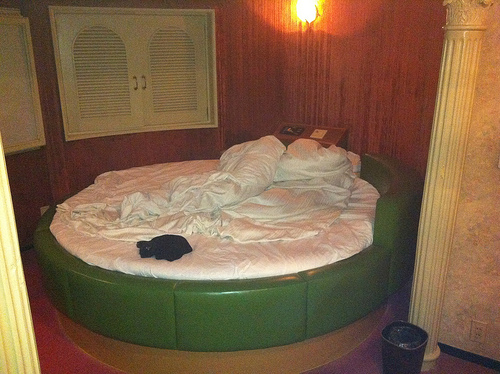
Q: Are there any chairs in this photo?
A: No, there are no chairs.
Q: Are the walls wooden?
A: Yes, the walls are wooden.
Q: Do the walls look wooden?
A: Yes, the walls are wooden.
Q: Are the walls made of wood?
A: Yes, the walls are made of wood.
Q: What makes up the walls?
A: The walls are made of wood.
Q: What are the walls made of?
A: The walls are made of wood.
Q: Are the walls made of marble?
A: No, the walls are made of wood.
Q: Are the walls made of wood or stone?
A: The walls are made of wood.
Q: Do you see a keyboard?
A: No, there are no keyboards.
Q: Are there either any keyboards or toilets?
A: No, there are no keyboards or toilets.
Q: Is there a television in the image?
A: No, there are no televisions.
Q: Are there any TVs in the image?
A: No, there are no tvs.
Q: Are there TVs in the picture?
A: No, there are no tvs.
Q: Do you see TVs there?
A: No, there are no tvs.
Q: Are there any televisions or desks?
A: No, there are no televisions or desks.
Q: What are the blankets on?
A: The blankets are on the bed.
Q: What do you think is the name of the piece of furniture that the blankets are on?
A: The piece of furniture is a bed.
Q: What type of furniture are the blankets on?
A: The blankets are on the bed.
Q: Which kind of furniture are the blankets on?
A: The blankets are on the bed.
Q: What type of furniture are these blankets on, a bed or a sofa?
A: The blankets are on a bed.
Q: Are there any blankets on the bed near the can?
A: Yes, there are blankets on the bed.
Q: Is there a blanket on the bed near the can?
A: Yes, there are blankets on the bed.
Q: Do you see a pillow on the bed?
A: No, there are blankets on the bed.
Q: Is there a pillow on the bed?
A: No, there are blankets on the bed.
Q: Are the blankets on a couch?
A: No, the blankets are on a bed.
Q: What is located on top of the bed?
A: The blankets are on top of the bed.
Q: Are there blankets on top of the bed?
A: Yes, there are blankets on top of the bed.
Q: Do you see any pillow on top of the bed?
A: No, there are blankets on top of the bed.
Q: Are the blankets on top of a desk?
A: No, the blankets are on top of the bed.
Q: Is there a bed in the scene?
A: Yes, there is a bed.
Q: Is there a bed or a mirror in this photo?
A: Yes, there is a bed.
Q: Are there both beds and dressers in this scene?
A: No, there is a bed but no dressers.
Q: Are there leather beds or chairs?
A: Yes, there is a leather bed.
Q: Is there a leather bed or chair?
A: Yes, there is a leather bed.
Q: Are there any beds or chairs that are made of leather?
A: Yes, the bed is made of leather.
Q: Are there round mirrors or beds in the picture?
A: Yes, there is a round bed.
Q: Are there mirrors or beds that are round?
A: Yes, the bed is round.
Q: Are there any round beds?
A: Yes, there is a round bed.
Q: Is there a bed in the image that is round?
A: Yes, there is a bed that is round.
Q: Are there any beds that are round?
A: Yes, there is a bed that is round.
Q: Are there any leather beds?
A: Yes, there is a bed that is made of leather.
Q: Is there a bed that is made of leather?
A: Yes, there is a bed that is made of leather.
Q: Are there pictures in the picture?
A: No, there are no pictures.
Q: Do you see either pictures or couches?
A: No, there are no pictures or couches.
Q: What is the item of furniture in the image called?
A: The piece of furniture is a bed.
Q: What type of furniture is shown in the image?
A: The furniture is a bed.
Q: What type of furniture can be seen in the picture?
A: The furniture is a bed.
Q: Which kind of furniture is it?
A: The piece of furniture is a bed.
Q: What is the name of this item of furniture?
A: This is a bed.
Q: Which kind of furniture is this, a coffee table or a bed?
A: This is a bed.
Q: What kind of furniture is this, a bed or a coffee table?
A: This is a bed.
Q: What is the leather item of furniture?
A: The piece of furniture is a bed.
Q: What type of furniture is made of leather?
A: The furniture is a bed.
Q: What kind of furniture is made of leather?
A: The furniture is a bed.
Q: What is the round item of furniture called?
A: The piece of furniture is a bed.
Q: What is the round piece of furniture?
A: The piece of furniture is a bed.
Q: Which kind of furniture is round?
A: The furniture is a bed.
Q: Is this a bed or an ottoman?
A: This is a bed.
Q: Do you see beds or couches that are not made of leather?
A: No, there is a bed but it is made of leather.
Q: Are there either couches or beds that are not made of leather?
A: No, there is a bed but it is made of leather.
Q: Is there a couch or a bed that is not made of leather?
A: No, there is a bed but it is made of leather.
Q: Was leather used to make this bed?
A: Yes, the bed is made of leather.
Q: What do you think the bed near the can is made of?
A: The bed is made of leather.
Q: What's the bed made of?
A: The bed is made of leather.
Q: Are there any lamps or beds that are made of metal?
A: No, there is a bed but it is made of leather.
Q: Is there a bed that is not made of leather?
A: No, there is a bed but it is made of leather.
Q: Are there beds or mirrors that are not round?
A: No, there is a bed but it is round.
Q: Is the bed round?
A: Yes, the bed is round.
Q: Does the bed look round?
A: Yes, the bed is round.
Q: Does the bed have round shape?
A: Yes, the bed is round.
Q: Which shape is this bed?
A: The bed is round.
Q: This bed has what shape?
A: The bed is round.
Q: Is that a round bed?
A: Yes, that is a round bed.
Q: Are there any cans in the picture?
A: Yes, there is a can.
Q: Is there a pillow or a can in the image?
A: Yes, there is a can.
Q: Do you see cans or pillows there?
A: Yes, there is a can.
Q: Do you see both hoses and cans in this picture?
A: No, there is a can but no hoses.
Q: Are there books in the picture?
A: No, there are no books.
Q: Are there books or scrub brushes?
A: No, there are no books or scrub brushes.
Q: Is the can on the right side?
A: Yes, the can is on the right of the image.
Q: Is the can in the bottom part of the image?
A: Yes, the can is in the bottom of the image.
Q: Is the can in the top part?
A: No, the can is in the bottom of the image.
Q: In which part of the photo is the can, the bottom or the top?
A: The can is in the bottom of the image.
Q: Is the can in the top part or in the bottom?
A: The can is in the bottom of the image.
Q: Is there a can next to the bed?
A: Yes, there is a can next to the bed.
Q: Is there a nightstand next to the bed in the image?
A: No, there is a can next to the bed.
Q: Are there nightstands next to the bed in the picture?
A: No, there is a can next to the bed.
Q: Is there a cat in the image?
A: Yes, there is a cat.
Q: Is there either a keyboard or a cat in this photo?
A: Yes, there is a cat.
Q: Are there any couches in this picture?
A: No, there are no couches.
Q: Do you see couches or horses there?
A: No, there are no couches or horses.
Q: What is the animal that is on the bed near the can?
A: The animal is a cat.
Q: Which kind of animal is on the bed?
A: The animal is a cat.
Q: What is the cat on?
A: The cat is on the bed.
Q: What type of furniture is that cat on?
A: The cat is on the bed.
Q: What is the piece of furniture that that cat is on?
A: The piece of furniture is a bed.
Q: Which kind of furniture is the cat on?
A: The cat is on the bed.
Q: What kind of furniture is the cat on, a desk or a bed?
A: The cat is on a bed.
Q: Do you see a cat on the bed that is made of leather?
A: Yes, there is a cat on the bed.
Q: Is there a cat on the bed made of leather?
A: Yes, there is a cat on the bed.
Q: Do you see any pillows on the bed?
A: No, there is a cat on the bed.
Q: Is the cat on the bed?
A: Yes, the cat is on the bed.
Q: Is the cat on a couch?
A: No, the cat is on the bed.